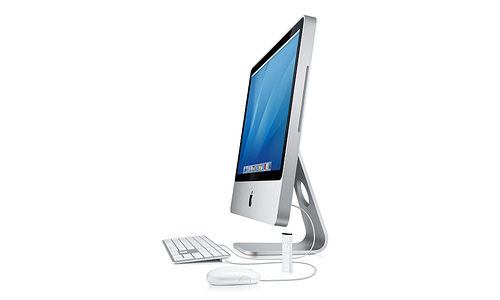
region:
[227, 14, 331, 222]
a flat screen monitor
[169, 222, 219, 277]
a white key pad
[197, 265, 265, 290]
a white mouse for computer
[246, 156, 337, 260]
a stand to hold monitor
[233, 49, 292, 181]
a blue screen on montor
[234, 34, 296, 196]
montior is turned on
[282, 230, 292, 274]
a usb for computer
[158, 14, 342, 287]
a group of computer parts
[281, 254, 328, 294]
wire to the computer mouse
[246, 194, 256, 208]
a design at the bottom of screen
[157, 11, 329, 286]
The Mac is silver.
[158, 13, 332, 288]
The Mac is in 3/4 profile.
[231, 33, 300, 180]
The screen is blue.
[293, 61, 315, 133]
The disk drive is on the monitor's side.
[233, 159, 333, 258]
The Mac stand has a curved angle.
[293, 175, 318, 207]
The Mac stand has a hole in the back.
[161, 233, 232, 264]
The keyboard has white keys.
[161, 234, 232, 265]
The keyboard is flat.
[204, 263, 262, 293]
The mouse is white.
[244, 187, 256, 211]
The Apple logo is black.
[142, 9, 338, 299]
An apple computer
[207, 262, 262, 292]
A mouse for a computer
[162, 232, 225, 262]
A keyboard for a computer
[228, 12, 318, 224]
A screen for a computer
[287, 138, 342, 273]
A stand for a computer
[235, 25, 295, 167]
Blue color on the screen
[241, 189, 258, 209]
An apple symbol on the monitor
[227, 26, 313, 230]
A monitor for a computer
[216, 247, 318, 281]
A cord for a mouse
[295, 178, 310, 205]
A hole in the stand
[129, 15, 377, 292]
apple flat screen computer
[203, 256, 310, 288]
white wired computer mouse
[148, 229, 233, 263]
flat silver grey computer keyboard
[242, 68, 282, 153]
blue desktop screen of computer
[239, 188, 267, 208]
black apple symbol on computer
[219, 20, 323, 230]
grey flat screen computer monitor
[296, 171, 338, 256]
computer base stand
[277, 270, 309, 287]
grey computer mouse cord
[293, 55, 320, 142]
side of computer disk drive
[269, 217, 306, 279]
usb plug drive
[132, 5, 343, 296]
an Apple computer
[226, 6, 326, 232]
an Apple computer monitor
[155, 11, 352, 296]
An Apple Imac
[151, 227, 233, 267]
an elegant Apple keyboard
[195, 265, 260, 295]
a white Apple mouse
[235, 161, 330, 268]
an Apple iMac stand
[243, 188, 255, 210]
the Apple company logo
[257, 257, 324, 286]
the cord on an Apple mouse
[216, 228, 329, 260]
the cord on an Apple keyboard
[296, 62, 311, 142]
a slot for the CD drive